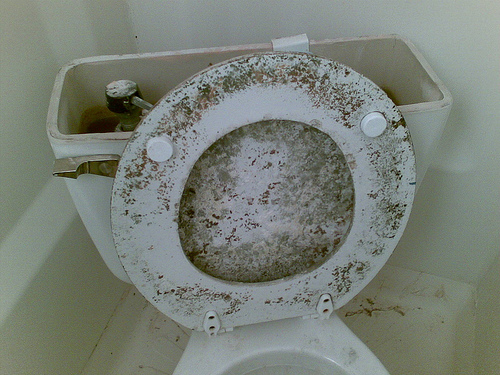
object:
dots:
[307, 181, 369, 292]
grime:
[138, 98, 394, 300]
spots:
[51, 152, 119, 180]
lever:
[51, 152, 124, 180]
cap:
[103, 79, 156, 115]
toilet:
[44, 32, 455, 375]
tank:
[46, 33, 456, 138]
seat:
[109, 48, 418, 338]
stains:
[172, 87, 214, 110]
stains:
[344, 299, 400, 320]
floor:
[391, 331, 436, 358]